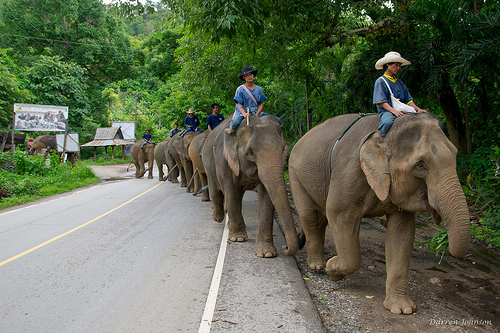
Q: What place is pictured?
A: It is a road.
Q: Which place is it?
A: It is a road.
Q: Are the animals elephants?
A: Yes, all the animals are elephants.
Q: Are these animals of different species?
A: No, all the animals are elephants.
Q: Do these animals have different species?
A: No, all the animals are elephants.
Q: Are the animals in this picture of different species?
A: No, all the animals are elephants.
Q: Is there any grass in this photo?
A: Yes, there is grass.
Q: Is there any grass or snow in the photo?
A: Yes, there is grass.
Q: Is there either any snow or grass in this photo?
A: Yes, there is grass.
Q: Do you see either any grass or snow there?
A: Yes, there is grass.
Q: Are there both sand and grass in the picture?
A: No, there is grass but no sand.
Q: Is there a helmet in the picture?
A: No, there are no helmets.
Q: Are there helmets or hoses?
A: No, there are no helmets or hoses.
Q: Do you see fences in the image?
A: No, there are no fences.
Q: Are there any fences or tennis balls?
A: No, there are no fences or tennis balls.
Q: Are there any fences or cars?
A: No, there are no fences or cars.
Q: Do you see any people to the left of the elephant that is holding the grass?
A: Yes, there are people to the left of the elephant.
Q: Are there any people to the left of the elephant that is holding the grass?
A: Yes, there are people to the left of the elephant.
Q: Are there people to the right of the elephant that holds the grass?
A: No, the people are to the left of the elephant.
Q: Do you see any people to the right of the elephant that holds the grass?
A: No, the people are to the left of the elephant.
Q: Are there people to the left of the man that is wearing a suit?
A: Yes, there are people to the left of the man.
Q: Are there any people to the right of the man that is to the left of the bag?
A: No, the people are to the left of the man.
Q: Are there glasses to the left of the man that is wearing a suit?
A: No, there are people to the left of the man.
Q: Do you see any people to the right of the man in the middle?
A: Yes, there are people to the right of the man.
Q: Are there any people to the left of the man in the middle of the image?
A: No, the people are to the right of the man.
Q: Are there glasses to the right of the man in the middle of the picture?
A: No, there are people to the right of the man.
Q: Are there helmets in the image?
A: No, there are no helmets.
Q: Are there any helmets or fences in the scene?
A: No, there are no helmets or fences.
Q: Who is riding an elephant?
A: The man is riding an elephant.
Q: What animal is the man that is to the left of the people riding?
A: The man is riding an elephant.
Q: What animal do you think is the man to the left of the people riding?
A: The man is riding an elephant.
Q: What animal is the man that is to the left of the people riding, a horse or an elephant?
A: The man is riding an elephant.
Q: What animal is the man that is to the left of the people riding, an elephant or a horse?
A: The man is riding an elephant.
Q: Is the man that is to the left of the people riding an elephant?
A: Yes, the man is riding an elephant.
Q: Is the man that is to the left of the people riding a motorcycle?
A: No, the man is riding an elephant.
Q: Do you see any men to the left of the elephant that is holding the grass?
A: Yes, there is a man to the left of the elephant.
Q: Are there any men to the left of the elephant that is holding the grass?
A: Yes, there is a man to the left of the elephant.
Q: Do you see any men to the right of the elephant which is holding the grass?
A: No, the man is to the left of the elephant.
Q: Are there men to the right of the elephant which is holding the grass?
A: No, the man is to the left of the elephant.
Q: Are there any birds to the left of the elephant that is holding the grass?
A: No, there is a man to the left of the elephant.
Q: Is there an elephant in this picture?
A: Yes, there is an elephant.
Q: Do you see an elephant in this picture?
A: Yes, there is an elephant.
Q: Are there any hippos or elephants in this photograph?
A: Yes, there is an elephant.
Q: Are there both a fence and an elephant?
A: No, there is an elephant but no fences.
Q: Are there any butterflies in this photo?
A: No, there are no butterflies.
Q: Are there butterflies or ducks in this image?
A: No, there are no butterflies or ducks.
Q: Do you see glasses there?
A: No, there are no glasses.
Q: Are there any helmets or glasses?
A: No, there are no glasses or helmets.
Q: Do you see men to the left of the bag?
A: Yes, there is a man to the left of the bag.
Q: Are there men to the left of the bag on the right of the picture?
A: Yes, there is a man to the left of the bag.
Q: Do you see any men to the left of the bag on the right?
A: Yes, there is a man to the left of the bag.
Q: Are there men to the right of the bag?
A: No, the man is to the left of the bag.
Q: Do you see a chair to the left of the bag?
A: No, there is a man to the left of the bag.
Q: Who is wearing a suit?
A: The man is wearing a suit.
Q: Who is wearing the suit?
A: The man is wearing a suit.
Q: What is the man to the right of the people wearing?
A: The man is wearing a suit.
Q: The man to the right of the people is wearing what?
A: The man is wearing a suit.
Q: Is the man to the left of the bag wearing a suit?
A: Yes, the man is wearing a suit.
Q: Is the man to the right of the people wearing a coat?
A: No, the man is wearing a suit.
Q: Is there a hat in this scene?
A: Yes, there is a hat.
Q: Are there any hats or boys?
A: Yes, there is a hat.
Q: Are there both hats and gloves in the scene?
A: No, there is a hat but no gloves.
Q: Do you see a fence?
A: No, there are no fences.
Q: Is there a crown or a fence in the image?
A: No, there are no fences or crowns.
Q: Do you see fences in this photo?
A: No, there are no fences.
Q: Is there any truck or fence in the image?
A: No, there are no fences or trucks.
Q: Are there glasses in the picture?
A: No, there are no glasses.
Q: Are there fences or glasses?
A: No, there are no glasses or fences.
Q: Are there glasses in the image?
A: No, there are no glasses.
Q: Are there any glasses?
A: No, there are no glasses.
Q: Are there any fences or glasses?
A: No, there are no glasses or fences.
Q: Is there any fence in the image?
A: No, there are no fences.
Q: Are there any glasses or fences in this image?
A: No, there are no fences or glasses.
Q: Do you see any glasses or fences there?
A: No, there are no fences or glasses.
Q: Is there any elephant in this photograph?
A: Yes, there is an elephant.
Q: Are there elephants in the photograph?
A: Yes, there is an elephant.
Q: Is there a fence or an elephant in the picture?
A: Yes, there is an elephant.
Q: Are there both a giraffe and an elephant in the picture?
A: No, there is an elephant but no giraffes.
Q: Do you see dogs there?
A: No, there are no dogs.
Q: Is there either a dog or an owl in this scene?
A: No, there are no dogs or owls.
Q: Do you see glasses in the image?
A: No, there are no glasses.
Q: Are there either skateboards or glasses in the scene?
A: No, there are no glasses or skateboards.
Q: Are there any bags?
A: Yes, there is a bag.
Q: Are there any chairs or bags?
A: Yes, there is a bag.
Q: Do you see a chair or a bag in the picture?
A: Yes, there is a bag.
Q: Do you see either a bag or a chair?
A: Yes, there is a bag.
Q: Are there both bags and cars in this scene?
A: No, there is a bag but no cars.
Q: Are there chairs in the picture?
A: No, there are no chairs.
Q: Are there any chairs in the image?
A: No, there are no chairs.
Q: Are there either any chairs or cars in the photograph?
A: No, there are no chairs or cars.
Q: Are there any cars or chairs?
A: No, there are no chairs or cars.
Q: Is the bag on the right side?
A: Yes, the bag is on the right of the image.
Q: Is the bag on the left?
A: No, the bag is on the right of the image.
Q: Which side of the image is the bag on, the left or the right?
A: The bag is on the right of the image.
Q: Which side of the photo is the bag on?
A: The bag is on the right of the image.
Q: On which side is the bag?
A: The bag is on the right of the image.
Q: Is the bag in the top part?
A: Yes, the bag is in the top of the image.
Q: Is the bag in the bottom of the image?
A: No, the bag is in the top of the image.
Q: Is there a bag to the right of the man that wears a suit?
A: Yes, there is a bag to the right of the man.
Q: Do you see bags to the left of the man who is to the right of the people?
A: No, the bag is to the right of the man.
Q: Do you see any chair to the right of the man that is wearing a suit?
A: No, there is a bag to the right of the man.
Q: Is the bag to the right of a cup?
A: No, the bag is to the right of a man.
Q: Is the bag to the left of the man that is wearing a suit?
A: No, the bag is to the right of the man.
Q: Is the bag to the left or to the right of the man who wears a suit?
A: The bag is to the right of the man.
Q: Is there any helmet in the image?
A: No, there are no helmets.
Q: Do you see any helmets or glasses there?
A: No, there are no helmets or glasses.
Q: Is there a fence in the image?
A: No, there are no fences.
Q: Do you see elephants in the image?
A: Yes, there is an elephant.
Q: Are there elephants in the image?
A: Yes, there is an elephant.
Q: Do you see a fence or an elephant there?
A: Yes, there is an elephant.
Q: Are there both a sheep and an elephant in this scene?
A: No, there is an elephant but no sheep.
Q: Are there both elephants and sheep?
A: No, there is an elephant but no sheep.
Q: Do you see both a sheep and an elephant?
A: No, there is an elephant but no sheep.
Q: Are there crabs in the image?
A: No, there are no crabs.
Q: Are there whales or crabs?
A: No, there are no crabs or whales.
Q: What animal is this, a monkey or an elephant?
A: This is an elephant.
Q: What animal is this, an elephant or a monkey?
A: This is an elephant.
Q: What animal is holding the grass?
A: The elephant is holding the grass.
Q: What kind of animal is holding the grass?
A: The animal is an elephant.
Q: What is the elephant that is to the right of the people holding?
A: The elephant is holding the grass.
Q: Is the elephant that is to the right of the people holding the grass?
A: Yes, the elephant is holding the grass.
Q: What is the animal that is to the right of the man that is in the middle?
A: The animal is an elephant.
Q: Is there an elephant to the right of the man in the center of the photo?
A: Yes, there is an elephant to the right of the man.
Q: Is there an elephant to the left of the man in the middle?
A: No, the elephant is to the right of the man.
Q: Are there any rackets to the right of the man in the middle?
A: No, there is an elephant to the right of the man.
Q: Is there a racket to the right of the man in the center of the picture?
A: No, there is an elephant to the right of the man.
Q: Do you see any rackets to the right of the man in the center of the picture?
A: No, there is an elephant to the right of the man.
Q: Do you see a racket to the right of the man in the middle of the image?
A: No, there is an elephant to the right of the man.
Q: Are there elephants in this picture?
A: Yes, there are elephants.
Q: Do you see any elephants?
A: Yes, there are elephants.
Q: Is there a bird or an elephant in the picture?
A: Yes, there are elephants.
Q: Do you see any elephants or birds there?
A: Yes, there are elephants.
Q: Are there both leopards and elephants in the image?
A: No, there are elephants but no leopards.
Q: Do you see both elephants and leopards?
A: No, there are elephants but no leopards.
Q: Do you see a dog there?
A: No, there are no dogs.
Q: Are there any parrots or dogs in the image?
A: No, there are no dogs or parrots.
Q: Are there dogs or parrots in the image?
A: No, there are no dogs or parrots.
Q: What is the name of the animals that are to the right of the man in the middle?
A: The animals are elephants.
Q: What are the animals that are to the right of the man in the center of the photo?
A: The animals are elephants.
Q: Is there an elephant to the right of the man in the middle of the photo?
A: Yes, there are elephants to the right of the man.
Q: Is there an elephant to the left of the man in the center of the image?
A: No, the elephants are to the right of the man.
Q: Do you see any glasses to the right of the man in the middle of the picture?
A: No, there are elephants to the right of the man.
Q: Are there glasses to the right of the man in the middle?
A: No, there are elephants to the right of the man.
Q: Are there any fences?
A: No, there are no fences.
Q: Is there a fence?
A: No, there are no fences.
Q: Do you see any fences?
A: No, there are no fences.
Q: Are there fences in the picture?
A: No, there are no fences.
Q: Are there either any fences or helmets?
A: No, there are no fences or helmets.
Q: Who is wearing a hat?
A: The man is wearing a hat.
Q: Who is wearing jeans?
A: The man is wearing jeans.